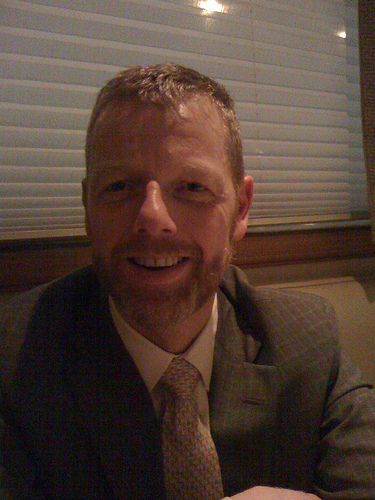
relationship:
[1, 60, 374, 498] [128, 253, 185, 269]
man has teeth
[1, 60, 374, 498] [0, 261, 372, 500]
man wearing suit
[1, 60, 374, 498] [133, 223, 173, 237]
man has nostrils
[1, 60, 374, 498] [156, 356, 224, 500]
man wearing tie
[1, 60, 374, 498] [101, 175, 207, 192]
man has eyes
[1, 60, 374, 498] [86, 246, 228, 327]
man has beard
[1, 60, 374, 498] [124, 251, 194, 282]
man has mouth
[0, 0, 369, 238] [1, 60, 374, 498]
blinds behind man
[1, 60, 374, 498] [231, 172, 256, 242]
man has ear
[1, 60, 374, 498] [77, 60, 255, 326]
man has head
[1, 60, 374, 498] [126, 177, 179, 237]
man has nose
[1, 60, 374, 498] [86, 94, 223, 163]
man has forehead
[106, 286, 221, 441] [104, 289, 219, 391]
shirt has collar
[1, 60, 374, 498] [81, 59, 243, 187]
man has hair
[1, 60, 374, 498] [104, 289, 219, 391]
man has collar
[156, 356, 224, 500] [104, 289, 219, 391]
tie underneath collar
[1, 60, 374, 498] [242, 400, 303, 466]
man has suit lapel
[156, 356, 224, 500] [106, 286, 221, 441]
tie on top of shirt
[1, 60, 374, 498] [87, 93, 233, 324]
man has face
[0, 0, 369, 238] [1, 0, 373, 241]
blinds hanging on window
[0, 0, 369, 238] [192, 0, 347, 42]
blinds reflecting light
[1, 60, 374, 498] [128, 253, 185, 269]
man showing teeth